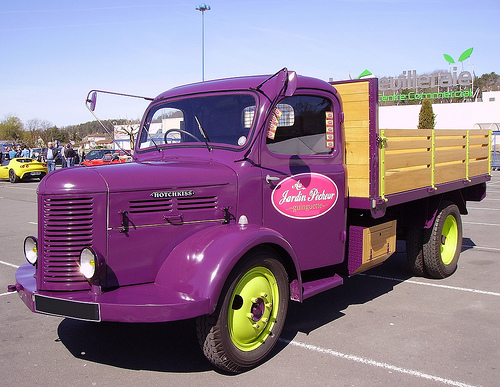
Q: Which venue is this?
A: This is a parking lot.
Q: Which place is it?
A: It is a parking lot.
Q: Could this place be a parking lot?
A: Yes, it is a parking lot.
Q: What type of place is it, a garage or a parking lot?
A: It is a parking lot.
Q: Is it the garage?
A: No, it is the parking lot.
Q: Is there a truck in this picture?
A: Yes, there is a truck.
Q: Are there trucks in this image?
A: Yes, there is a truck.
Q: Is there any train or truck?
A: Yes, there is a truck.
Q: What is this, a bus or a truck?
A: This is a truck.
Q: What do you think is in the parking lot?
A: The truck is in the parking lot.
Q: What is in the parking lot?
A: The truck is in the parking lot.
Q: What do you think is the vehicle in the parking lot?
A: The vehicle is a truck.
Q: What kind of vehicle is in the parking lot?
A: The vehicle is a truck.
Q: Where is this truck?
A: The truck is in the parking lot.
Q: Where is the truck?
A: The truck is in the parking lot.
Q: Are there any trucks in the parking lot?
A: Yes, there is a truck in the parking lot.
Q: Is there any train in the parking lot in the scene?
A: No, there is a truck in the parking lot.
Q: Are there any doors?
A: Yes, there is a door.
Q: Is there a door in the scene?
A: Yes, there is a door.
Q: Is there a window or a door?
A: Yes, there is a door.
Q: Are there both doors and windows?
A: Yes, there are both a door and windows.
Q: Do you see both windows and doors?
A: Yes, there are both a door and windows.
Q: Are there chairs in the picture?
A: No, there are no chairs.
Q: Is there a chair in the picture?
A: No, there are no chairs.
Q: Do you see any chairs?
A: No, there are no chairs.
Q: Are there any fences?
A: No, there are no fences.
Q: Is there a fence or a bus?
A: No, there are no fences or buses.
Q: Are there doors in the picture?
A: Yes, there is a door.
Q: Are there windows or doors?
A: Yes, there is a door.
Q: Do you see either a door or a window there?
A: Yes, there is a door.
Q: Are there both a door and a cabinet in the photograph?
A: No, there is a door but no cabinets.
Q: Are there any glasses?
A: No, there are no glasses.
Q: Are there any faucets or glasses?
A: No, there are no glasses or faucets.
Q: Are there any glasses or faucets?
A: No, there are no glasses or faucets.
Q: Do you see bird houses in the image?
A: No, there are no bird houses.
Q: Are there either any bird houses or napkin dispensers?
A: No, there are no bird houses or napkin dispensers.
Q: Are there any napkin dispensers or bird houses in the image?
A: No, there are no bird houses or napkin dispensers.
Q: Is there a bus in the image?
A: No, there are no buses.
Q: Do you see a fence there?
A: No, there are no fences.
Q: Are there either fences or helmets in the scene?
A: No, there are no fences or helmets.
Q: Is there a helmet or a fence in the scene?
A: No, there are no fences or helmets.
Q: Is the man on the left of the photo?
A: Yes, the man is on the left of the image.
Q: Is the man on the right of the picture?
A: No, the man is on the left of the image.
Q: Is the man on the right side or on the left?
A: The man is on the left of the image.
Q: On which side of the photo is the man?
A: The man is on the left of the image.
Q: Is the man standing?
A: Yes, the man is standing.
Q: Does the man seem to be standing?
A: Yes, the man is standing.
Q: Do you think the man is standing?
A: Yes, the man is standing.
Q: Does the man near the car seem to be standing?
A: Yes, the man is standing.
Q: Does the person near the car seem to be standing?
A: Yes, the man is standing.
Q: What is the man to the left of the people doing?
A: The man is standing.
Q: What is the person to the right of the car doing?
A: The man is standing.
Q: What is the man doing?
A: The man is standing.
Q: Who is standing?
A: The man is standing.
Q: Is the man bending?
A: No, the man is standing.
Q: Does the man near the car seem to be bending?
A: No, the man is standing.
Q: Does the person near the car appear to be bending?
A: No, the man is standing.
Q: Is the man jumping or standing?
A: The man is standing.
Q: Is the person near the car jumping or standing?
A: The man is standing.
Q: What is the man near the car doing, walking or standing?
A: The man is standing.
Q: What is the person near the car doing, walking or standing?
A: The man is standing.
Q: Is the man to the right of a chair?
A: No, the man is to the right of the car.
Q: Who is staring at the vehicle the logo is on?
A: The man is staring at the truck.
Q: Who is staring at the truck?
A: The man is staring at the truck.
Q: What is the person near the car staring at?
A: The man is staring at the truck.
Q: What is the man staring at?
A: The man is staring at the truck.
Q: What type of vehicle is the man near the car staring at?
A: The man is staring at the truck.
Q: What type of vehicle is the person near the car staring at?
A: The man is staring at the truck.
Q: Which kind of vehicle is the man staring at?
A: The man is staring at the truck.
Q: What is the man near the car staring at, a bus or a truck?
A: The man is staring at a truck.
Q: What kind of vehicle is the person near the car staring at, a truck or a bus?
A: The man is staring at a truck.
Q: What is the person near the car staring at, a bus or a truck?
A: The man is staring at a truck.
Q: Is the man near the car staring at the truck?
A: Yes, the man is staring at the truck.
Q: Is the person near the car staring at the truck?
A: Yes, the man is staring at the truck.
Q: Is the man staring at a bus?
A: No, the man is staring at the truck.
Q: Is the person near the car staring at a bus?
A: No, the man is staring at the truck.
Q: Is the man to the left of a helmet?
A: No, the man is to the left of the car.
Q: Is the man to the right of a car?
A: No, the man is to the left of a car.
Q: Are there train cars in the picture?
A: No, there are no train cars.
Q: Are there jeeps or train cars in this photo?
A: No, there are no train cars or jeeps.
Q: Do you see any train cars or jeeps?
A: No, there are no train cars or jeeps.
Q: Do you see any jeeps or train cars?
A: No, there are no train cars or jeeps.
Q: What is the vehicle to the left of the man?
A: The vehicle is a car.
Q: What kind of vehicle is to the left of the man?
A: The vehicle is a car.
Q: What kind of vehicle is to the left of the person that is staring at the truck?
A: The vehicle is a car.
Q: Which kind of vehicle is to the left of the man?
A: The vehicle is a car.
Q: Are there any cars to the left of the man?
A: Yes, there is a car to the left of the man.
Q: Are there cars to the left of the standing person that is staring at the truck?
A: Yes, there is a car to the left of the man.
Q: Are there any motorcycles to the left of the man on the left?
A: No, there is a car to the left of the man.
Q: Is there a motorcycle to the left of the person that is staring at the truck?
A: No, there is a car to the left of the man.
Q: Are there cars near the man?
A: Yes, there is a car near the man.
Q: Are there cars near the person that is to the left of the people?
A: Yes, there is a car near the man.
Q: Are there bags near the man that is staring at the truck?
A: No, there is a car near the man.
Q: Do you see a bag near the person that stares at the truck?
A: No, there is a car near the man.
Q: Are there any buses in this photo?
A: No, there are no buses.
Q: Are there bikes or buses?
A: No, there are no buses or bikes.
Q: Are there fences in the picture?
A: No, there are no fences.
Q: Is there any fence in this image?
A: No, there are no fences.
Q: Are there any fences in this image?
A: No, there are no fences.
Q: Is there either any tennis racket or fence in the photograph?
A: No, there are no fences or rackets.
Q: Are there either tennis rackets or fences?
A: No, there are no fences or tennis rackets.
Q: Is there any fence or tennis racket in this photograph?
A: No, there are no fences or rackets.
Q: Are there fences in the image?
A: No, there are no fences.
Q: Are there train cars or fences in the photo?
A: No, there are no fences or train cars.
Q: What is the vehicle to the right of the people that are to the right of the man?
A: The vehicle is a car.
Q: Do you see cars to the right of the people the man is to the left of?
A: Yes, there is a car to the right of the people.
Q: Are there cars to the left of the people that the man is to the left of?
A: No, the car is to the right of the people.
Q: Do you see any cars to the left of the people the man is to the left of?
A: No, the car is to the right of the people.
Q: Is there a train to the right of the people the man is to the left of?
A: No, there is a car to the right of the people.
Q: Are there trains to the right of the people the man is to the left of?
A: No, there is a car to the right of the people.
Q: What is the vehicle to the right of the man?
A: The vehicle is a car.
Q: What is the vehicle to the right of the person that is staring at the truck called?
A: The vehicle is a car.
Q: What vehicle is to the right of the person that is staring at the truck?
A: The vehicle is a car.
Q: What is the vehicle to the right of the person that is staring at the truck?
A: The vehicle is a car.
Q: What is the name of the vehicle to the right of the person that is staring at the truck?
A: The vehicle is a car.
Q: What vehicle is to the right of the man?
A: The vehicle is a car.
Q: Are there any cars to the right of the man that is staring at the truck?
A: Yes, there is a car to the right of the man.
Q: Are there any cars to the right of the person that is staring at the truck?
A: Yes, there is a car to the right of the man.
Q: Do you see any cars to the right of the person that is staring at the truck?
A: Yes, there is a car to the right of the man.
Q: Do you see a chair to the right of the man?
A: No, there is a car to the right of the man.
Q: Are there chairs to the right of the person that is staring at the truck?
A: No, there is a car to the right of the man.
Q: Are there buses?
A: No, there are no buses.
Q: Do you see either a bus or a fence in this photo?
A: No, there are no buses or fences.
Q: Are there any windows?
A: Yes, there is a window.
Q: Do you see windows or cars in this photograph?
A: Yes, there is a window.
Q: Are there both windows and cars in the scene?
A: Yes, there are both a window and a car.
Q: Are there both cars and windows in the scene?
A: Yes, there are both a window and a car.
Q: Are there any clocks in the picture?
A: No, there are no clocks.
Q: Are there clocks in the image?
A: No, there are no clocks.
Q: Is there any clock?
A: No, there are no clocks.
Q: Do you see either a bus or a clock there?
A: No, there are no clocks or buses.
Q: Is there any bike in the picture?
A: No, there are no bikes.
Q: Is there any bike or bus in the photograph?
A: No, there are no bikes or buses.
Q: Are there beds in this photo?
A: Yes, there is a bed.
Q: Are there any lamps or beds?
A: Yes, there is a bed.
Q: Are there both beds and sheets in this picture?
A: No, there is a bed but no sheets.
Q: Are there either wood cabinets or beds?
A: Yes, there is a wood bed.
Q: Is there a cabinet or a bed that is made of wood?
A: Yes, the bed is made of wood.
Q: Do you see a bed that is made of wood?
A: Yes, there is a bed that is made of wood.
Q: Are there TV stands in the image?
A: No, there are no TV stands.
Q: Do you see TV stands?
A: No, there are no TV stands.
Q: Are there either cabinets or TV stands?
A: No, there are no TV stands or cabinets.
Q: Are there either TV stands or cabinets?
A: No, there are no TV stands or cabinets.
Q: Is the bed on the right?
A: Yes, the bed is on the right of the image.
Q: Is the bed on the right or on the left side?
A: The bed is on the right of the image.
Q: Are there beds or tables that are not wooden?
A: No, there is a bed but it is wooden.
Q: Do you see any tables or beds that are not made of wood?
A: No, there is a bed but it is made of wood.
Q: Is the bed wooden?
A: Yes, the bed is wooden.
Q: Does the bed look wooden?
A: Yes, the bed is wooden.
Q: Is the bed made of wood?
A: Yes, the bed is made of wood.